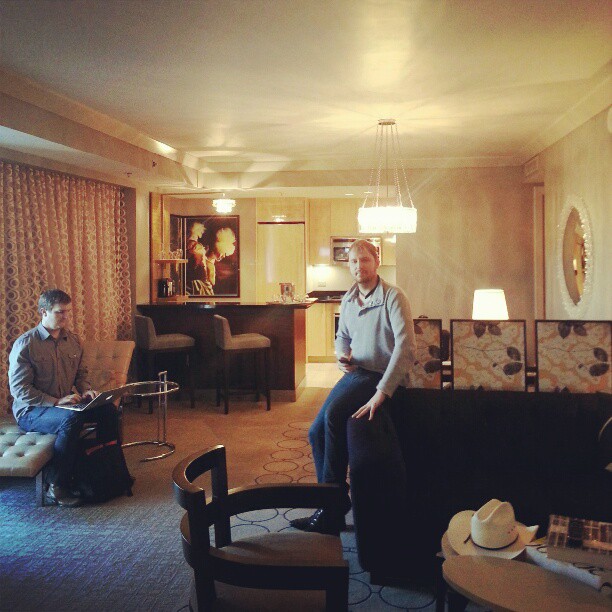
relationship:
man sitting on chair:
[309, 236, 411, 536] [346, 392, 611, 586]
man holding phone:
[309, 236, 411, 536] [336, 353, 360, 374]